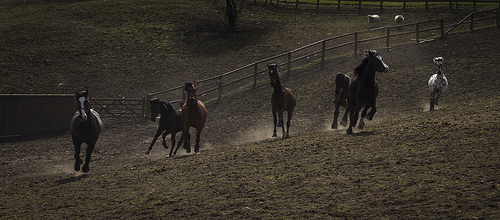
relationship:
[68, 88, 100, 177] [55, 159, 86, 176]
horse kicking up dust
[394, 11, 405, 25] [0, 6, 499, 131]
sheep behind fence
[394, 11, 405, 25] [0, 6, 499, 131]
sheep in fence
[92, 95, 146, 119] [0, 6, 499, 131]
door on fence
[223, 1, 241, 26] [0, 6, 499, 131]
tree trunk behind fence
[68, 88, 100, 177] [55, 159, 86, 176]
horse kicked up dust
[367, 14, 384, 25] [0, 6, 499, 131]
sheep behind fence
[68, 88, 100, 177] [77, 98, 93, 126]
horse has nose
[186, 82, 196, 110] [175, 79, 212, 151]
head of horse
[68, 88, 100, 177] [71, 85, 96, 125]
horse has head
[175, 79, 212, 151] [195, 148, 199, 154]
horse has hoof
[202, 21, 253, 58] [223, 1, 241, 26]
shadow of tree trunk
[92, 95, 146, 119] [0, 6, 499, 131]
door for fence